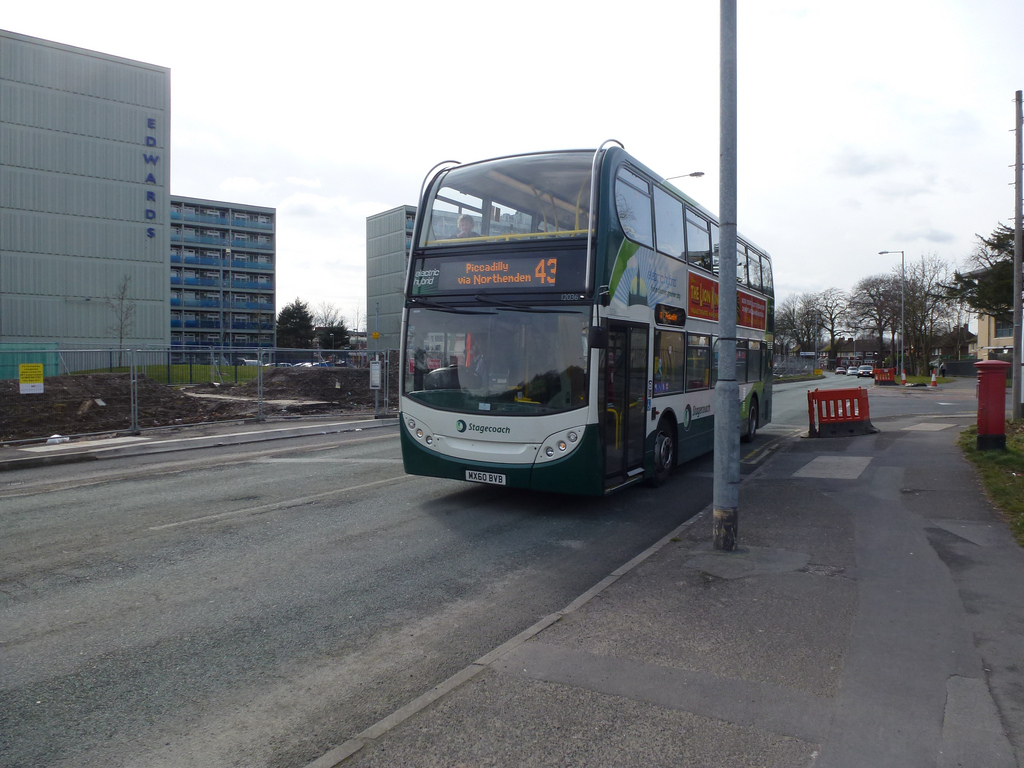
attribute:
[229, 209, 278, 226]
balcony — blue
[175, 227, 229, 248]
balcony — blue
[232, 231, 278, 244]
balcony — blue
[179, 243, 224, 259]
balcony — blue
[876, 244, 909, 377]
light pole — curved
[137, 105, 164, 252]
word — vertical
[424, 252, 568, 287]
display — digital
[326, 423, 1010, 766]
sidewalk — city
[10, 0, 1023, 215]
sky — white color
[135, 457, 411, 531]
lines — white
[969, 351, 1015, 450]
pillar — red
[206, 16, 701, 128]
clouds — white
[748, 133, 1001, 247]
clouds — white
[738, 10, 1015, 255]
clouds — white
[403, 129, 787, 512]
bus — passenger, double deck, white, green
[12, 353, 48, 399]
fence — yellow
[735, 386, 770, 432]
wheel — back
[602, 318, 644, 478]
door — closed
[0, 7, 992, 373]
sky — blue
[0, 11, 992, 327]
sky — blue